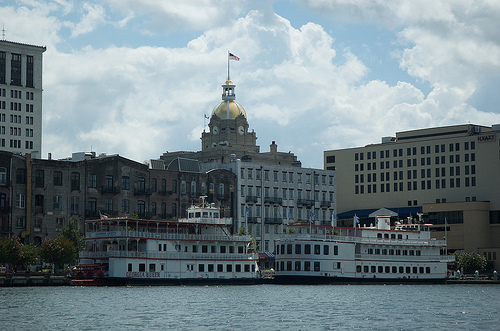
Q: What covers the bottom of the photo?
A: Water.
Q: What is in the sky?
A: Clouds.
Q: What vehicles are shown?
A: Boats.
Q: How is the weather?
A: Partly cloudy.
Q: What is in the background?
A: Buildings.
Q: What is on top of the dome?
A: A flag.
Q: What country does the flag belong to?
A: The united states.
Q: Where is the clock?
A: On the middle building.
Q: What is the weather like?
A: Partly cloudy.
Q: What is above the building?
A: The sky.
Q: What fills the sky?
A: Clouds.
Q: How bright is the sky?
A: Very bright.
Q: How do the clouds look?
A: White and puffy.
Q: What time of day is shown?
A: Afternoon.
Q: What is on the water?
A: Boats.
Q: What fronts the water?
A: Buildings.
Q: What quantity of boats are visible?
A: Two.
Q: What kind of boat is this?
A: Ferry boat.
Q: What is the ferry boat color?
A: White.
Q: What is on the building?
A: American flag.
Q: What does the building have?
A: Domed top.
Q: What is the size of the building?
A: Tall.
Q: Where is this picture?
A: By a river.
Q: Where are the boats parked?
A: Dock.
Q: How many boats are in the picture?
A: Two.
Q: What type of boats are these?
A: Paddle boats.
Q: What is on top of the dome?
A: U.S. flag.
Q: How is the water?
A: Calm.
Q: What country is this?
A: United states.